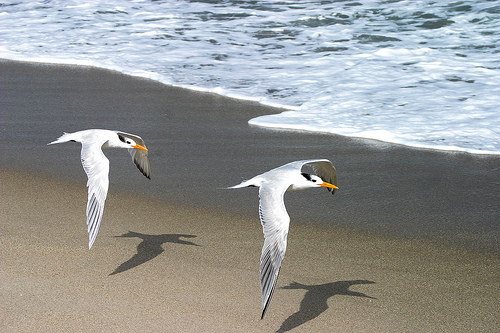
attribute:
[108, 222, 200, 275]
shadow — wet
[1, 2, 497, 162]
sea water — foamy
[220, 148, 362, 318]
bird — white 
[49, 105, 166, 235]
bird — white 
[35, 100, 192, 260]
seagull — flying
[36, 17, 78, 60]
sand — brown, wet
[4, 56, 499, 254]
sand — wet , brown 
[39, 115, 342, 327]
birds — flying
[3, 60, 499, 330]
sand — wet, brown, dry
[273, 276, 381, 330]
shadow — grey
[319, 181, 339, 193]
beak — yellow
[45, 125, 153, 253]
bird — white 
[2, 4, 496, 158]
waves — gentle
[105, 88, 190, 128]
sand — wet, brown 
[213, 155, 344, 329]
bird — white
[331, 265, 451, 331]
sand — brown, wet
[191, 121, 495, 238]
sand — brown, wet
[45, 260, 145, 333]
sand — brown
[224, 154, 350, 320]
seagull — flying